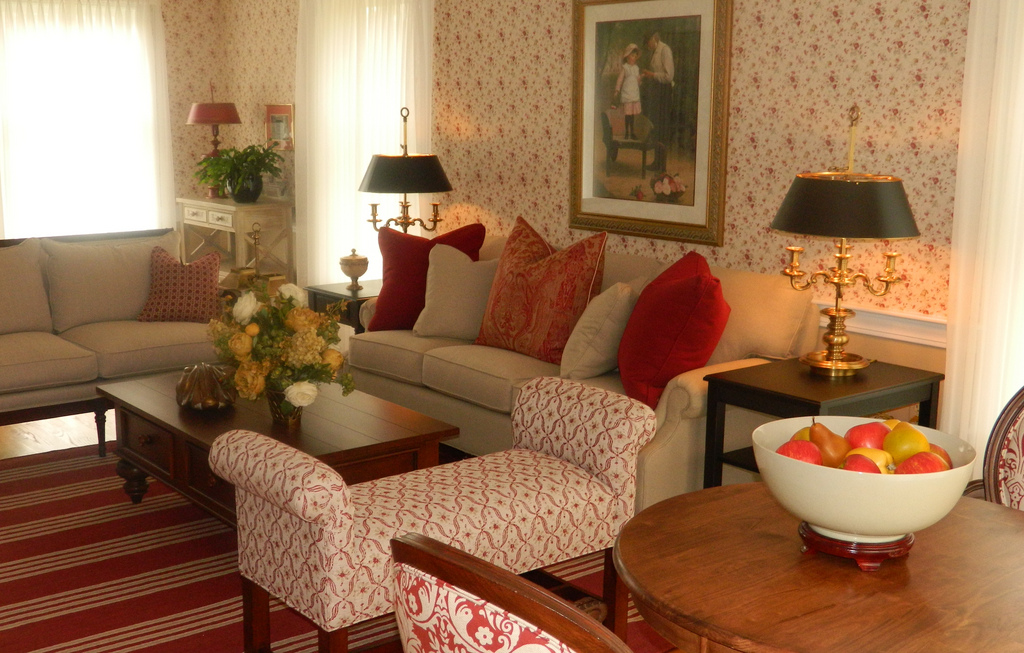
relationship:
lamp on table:
[768, 161, 922, 384] [704, 351, 944, 505]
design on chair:
[458, 596, 528, 649] [379, 526, 638, 648]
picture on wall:
[571, 1, 740, 254] [437, 7, 960, 314]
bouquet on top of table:
[215, 281, 367, 416] [89, 351, 465, 509]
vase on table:
[262, 343, 314, 428] [94, 351, 457, 475]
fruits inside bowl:
[783, 411, 952, 478] [751, 415, 978, 545]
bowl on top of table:
[751, 415, 978, 545] [617, 481, 1021, 648]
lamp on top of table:
[768, 161, 922, 384] [704, 355, 949, 487]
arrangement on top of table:
[167, 251, 364, 429] [57, 324, 451, 504]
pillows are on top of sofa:
[353, 212, 727, 375] [303, 195, 794, 481]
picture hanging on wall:
[571, 1, 724, 248] [413, 39, 960, 362]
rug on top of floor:
[22, 476, 223, 649] [5, 385, 699, 649]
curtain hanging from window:
[275, 13, 440, 312] [286, 18, 440, 330]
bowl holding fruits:
[751, 415, 978, 545] [776, 413, 954, 463]